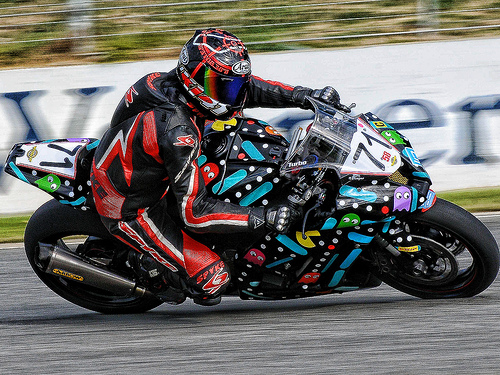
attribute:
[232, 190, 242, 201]
dot — white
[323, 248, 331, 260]
dot — white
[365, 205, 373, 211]
dot — white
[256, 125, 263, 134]
dot — white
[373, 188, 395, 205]
dot motorcycle — white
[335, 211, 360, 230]
ghost — colorful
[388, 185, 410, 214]
ghost — colorful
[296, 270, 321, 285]
ghost — colorful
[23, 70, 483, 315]
motorcycle — white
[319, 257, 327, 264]
dot — white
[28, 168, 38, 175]
dot — white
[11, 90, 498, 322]
motorcycle — black, blue, fast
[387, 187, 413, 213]
ghost — purple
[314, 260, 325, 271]
dot — white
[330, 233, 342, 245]
dot — white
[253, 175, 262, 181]
dot — white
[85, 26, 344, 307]
motorcyclist — wearing red and black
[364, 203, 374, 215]
dot — white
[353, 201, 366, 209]
dot — white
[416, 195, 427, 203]
dot — white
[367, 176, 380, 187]
dot — white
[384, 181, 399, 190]
dot — white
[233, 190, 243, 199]
dot — white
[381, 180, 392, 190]
dot — white